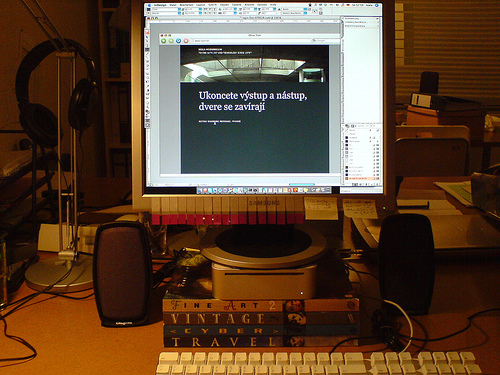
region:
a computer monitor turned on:
[87, 18, 498, 255]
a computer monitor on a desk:
[69, 25, 492, 301]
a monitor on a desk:
[92, 16, 494, 340]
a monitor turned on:
[82, 32, 470, 278]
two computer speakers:
[34, 166, 490, 350]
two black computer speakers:
[52, 176, 440, 374]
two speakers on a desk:
[24, 136, 496, 353]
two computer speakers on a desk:
[65, 161, 497, 338]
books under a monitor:
[114, 203, 464, 370]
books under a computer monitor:
[79, 54, 467, 311]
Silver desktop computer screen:
[127, 3, 396, 220]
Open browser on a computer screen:
[141, 3, 383, 194]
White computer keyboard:
[152, 347, 478, 374]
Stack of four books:
[159, 256, 361, 346]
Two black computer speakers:
[87, 210, 435, 327]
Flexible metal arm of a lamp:
[20, 1, 95, 295]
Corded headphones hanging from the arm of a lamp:
[0, 33, 102, 370]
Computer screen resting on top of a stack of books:
[127, 1, 397, 347]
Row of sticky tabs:
[148, 194, 304, 228]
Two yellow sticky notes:
[302, 193, 378, 221]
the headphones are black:
[16, 32, 105, 141]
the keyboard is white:
[153, 349, 478, 374]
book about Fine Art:
[165, 298, 353, 310]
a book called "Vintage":
[163, 312, 356, 324]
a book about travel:
[166, 330, 358, 349]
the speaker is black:
[95, 221, 151, 328]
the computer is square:
[143, 3, 389, 205]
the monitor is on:
[131, 3, 395, 210]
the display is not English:
[193, 87, 313, 118]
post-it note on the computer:
[302, 190, 338, 221]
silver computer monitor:
[130, 2, 395, 224]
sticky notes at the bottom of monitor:
[151, 195, 378, 228]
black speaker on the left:
[92, 225, 150, 325]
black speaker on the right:
[380, 213, 433, 313]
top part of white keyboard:
[155, 348, 484, 373]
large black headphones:
[14, 38, 95, 149]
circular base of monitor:
[201, 222, 327, 265]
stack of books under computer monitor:
[162, 246, 359, 347]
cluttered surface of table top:
[0, 176, 497, 373]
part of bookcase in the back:
[96, 3, 139, 183]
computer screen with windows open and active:
[127, 3, 392, 223]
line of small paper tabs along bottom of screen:
[142, 196, 304, 228]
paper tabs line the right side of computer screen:
[385, 0, 413, 73]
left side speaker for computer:
[92, 223, 163, 329]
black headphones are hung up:
[13, 36, 96, 142]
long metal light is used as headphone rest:
[29, 3, 97, 290]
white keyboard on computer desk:
[150, 347, 482, 373]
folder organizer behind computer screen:
[395, 120, 474, 180]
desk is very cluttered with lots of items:
[2, 0, 497, 372]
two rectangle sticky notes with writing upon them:
[303, 196, 379, 222]